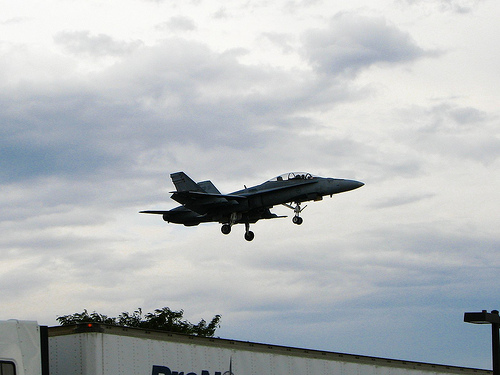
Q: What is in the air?
A: A plane.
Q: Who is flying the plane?
A: A pilot.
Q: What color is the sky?
A: Blue.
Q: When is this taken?
A: During the day.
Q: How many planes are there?
A: One.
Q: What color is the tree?
A: Green.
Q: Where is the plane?
A: In the air.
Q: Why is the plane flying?
A: To reach a destination.